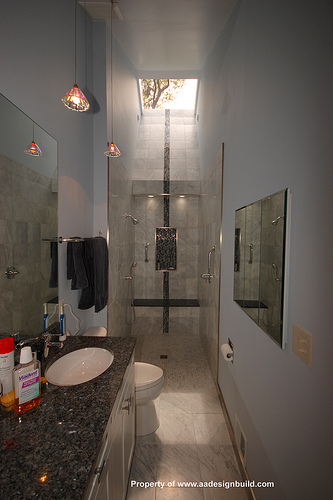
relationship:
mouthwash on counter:
[12, 345, 39, 413] [6, 418, 83, 496]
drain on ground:
[159, 352, 167, 361] [174, 343, 198, 383]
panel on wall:
[132, 68, 203, 128] [240, 369, 318, 426]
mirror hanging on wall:
[3, 215, 52, 286] [291, 215, 322, 284]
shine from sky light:
[126, 67, 222, 183] [131, 69, 205, 125]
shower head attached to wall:
[124, 211, 139, 225] [106, 29, 132, 342]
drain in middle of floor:
[158, 352, 167, 361] [134, 332, 248, 496]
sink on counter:
[47, 334, 111, 393] [56, 334, 134, 447]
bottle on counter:
[18, 343, 50, 413] [44, 385, 119, 461]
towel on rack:
[66, 235, 109, 313] [56, 232, 97, 245]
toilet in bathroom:
[79, 323, 164, 439] [1, 0, 332, 499]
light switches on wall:
[290, 323, 311, 362] [283, 275, 330, 341]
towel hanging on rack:
[66, 235, 109, 313] [59, 231, 112, 245]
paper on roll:
[220, 343, 234, 363] [193, 336, 255, 365]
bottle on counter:
[13, 343, 42, 417] [0, 370, 127, 498]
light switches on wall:
[291, 321, 313, 363] [218, 38, 329, 395]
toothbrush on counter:
[56, 297, 70, 344] [2, 330, 142, 498]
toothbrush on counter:
[37, 297, 52, 344] [2, 330, 142, 498]